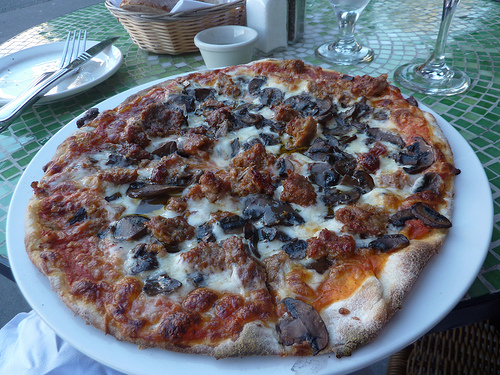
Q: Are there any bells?
A: No, there are no bells.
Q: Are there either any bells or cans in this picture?
A: No, there are no bells or cans.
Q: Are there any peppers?
A: No, there are no peppers.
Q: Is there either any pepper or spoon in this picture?
A: No, there are no peppers or spoons.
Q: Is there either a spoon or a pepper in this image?
A: No, there are no peppers or spoons.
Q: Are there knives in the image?
A: Yes, there is a knife.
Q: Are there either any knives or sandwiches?
A: Yes, there is a knife.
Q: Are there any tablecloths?
A: No, there are no tablecloths.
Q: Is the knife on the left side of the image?
A: Yes, the knife is on the left of the image.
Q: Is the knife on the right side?
A: No, the knife is on the left of the image.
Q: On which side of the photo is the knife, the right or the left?
A: The knife is on the left of the image.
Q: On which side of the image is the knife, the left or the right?
A: The knife is on the left of the image.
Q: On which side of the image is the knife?
A: The knife is on the left of the image.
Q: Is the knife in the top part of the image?
A: Yes, the knife is in the top of the image.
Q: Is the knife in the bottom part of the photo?
A: No, the knife is in the top of the image.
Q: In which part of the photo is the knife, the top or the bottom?
A: The knife is in the top of the image.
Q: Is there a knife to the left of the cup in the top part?
A: Yes, there is a knife to the left of the cup.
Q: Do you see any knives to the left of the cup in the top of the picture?
A: Yes, there is a knife to the left of the cup.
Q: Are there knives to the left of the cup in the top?
A: Yes, there is a knife to the left of the cup.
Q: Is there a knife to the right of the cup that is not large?
A: No, the knife is to the left of the cup.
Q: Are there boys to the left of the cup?
A: No, there is a knife to the left of the cup.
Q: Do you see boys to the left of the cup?
A: No, there is a knife to the left of the cup.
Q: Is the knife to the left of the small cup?
A: Yes, the knife is to the left of the cup.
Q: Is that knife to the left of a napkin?
A: No, the knife is to the left of the cup.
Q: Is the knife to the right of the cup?
A: No, the knife is to the left of the cup.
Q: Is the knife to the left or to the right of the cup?
A: The knife is to the left of the cup.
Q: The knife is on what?
A: The knife is on the plate.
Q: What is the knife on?
A: The knife is on the plate.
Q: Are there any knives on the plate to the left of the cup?
A: Yes, there is a knife on the plate.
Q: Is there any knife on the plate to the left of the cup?
A: Yes, there is a knife on the plate.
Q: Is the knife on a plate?
A: Yes, the knife is on a plate.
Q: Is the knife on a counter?
A: No, the knife is on a plate.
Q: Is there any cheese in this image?
A: Yes, there is cheese.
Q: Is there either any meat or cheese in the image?
A: Yes, there is cheese.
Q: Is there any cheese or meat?
A: Yes, there is cheese.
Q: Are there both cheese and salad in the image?
A: No, there is cheese but no salad.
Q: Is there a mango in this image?
A: No, there are no mangoes.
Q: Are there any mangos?
A: No, there are no mangos.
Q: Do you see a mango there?
A: No, there are no mangoes.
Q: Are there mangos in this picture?
A: No, there are no mangos.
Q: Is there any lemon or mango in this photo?
A: No, there are no mangoes or lemons.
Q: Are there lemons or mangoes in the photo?
A: No, there are no mangoes or lemons.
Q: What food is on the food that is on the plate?
A: The food is cheese.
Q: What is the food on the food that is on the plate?
A: The food is cheese.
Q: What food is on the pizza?
A: The food is cheese.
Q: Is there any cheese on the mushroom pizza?
A: Yes, there is cheese on the pizza.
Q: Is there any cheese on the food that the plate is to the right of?
A: Yes, there is cheese on the pizza.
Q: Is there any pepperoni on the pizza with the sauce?
A: No, there is cheese on the pizza.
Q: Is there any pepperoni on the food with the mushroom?
A: No, there is cheese on the pizza.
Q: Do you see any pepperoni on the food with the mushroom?
A: No, there is cheese on the pizza.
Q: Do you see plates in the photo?
A: Yes, there is a plate.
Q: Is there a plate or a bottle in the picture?
A: Yes, there is a plate.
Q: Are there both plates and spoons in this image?
A: No, there is a plate but no spoons.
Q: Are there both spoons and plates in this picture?
A: No, there is a plate but no spoons.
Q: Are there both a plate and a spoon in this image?
A: No, there is a plate but no spoons.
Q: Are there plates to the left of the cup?
A: Yes, there is a plate to the left of the cup.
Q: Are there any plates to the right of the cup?
A: No, the plate is to the left of the cup.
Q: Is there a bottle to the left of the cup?
A: No, there is a plate to the left of the cup.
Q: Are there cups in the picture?
A: Yes, there is a cup.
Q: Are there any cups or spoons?
A: Yes, there is a cup.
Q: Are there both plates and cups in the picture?
A: Yes, there are both a cup and a plate.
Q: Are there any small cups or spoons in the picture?
A: Yes, there is a small cup.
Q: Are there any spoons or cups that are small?
A: Yes, the cup is small.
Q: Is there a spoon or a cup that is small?
A: Yes, the cup is small.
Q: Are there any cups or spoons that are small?
A: Yes, the cup is small.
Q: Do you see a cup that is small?
A: Yes, there is a small cup.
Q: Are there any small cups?
A: Yes, there is a small cup.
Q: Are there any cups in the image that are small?
A: Yes, there is a cup that is small.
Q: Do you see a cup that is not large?
A: Yes, there is a small cup.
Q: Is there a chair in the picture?
A: No, there are no chairs.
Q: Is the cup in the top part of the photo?
A: Yes, the cup is in the top of the image.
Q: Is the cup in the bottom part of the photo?
A: No, the cup is in the top of the image.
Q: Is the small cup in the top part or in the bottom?
A: The cup is in the top of the image.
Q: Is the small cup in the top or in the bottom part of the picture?
A: The cup is in the top of the image.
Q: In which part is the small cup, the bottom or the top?
A: The cup is in the top of the image.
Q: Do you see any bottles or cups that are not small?
A: No, there is a cup but it is small.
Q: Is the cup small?
A: Yes, the cup is small.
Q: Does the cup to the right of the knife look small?
A: Yes, the cup is small.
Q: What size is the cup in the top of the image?
A: The cup is small.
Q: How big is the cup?
A: The cup is small.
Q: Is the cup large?
A: No, the cup is small.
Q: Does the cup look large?
A: No, the cup is small.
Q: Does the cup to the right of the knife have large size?
A: No, the cup is small.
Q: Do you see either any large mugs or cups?
A: No, there is a cup but it is small.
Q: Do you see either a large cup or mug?
A: No, there is a cup but it is small.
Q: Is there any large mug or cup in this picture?
A: No, there is a cup but it is small.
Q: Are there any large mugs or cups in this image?
A: No, there is a cup but it is small.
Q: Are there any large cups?
A: No, there is a cup but it is small.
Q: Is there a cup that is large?
A: No, there is a cup but it is small.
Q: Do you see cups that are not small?
A: No, there is a cup but it is small.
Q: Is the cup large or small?
A: The cup is small.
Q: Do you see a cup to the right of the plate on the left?
A: Yes, there is a cup to the right of the plate.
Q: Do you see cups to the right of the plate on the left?
A: Yes, there is a cup to the right of the plate.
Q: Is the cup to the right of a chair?
A: No, the cup is to the right of the plate.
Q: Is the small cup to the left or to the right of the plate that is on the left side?
A: The cup is to the right of the plate.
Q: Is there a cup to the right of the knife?
A: Yes, there is a cup to the right of the knife.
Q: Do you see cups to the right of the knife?
A: Yes, there is a cup to the right of the knife.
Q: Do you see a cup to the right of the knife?
A: Yes, there is a cup to the right of the knife.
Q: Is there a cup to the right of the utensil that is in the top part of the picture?
A: Yes, there is a cup to the right of the knife.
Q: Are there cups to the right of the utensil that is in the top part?
A: Yes, there is a cup to the right of the knife.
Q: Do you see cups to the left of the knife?
A: No, the cup is to the right of the knife.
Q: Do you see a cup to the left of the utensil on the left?
A: No, the cup is to the right of the knife.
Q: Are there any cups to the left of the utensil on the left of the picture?
A: No, the cup is to the right of the knife.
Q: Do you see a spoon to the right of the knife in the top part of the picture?
A: No, there is a cup to the right of the knife.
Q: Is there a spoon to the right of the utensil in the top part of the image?
A: No, there is a cup to the right of the knife.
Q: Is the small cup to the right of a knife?
A: Yes, the cup is to the right of a knife.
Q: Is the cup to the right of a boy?
A: No, the cup is to the right of a knife.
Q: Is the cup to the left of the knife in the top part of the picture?
A: No, the cup is to the right of the knife.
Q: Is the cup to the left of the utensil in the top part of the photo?
A: No, the cup is to the right of the knife.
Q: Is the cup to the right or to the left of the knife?
A: The cup is to the right of the knife.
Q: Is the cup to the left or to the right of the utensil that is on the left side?
A: The cup is to the right of the knife.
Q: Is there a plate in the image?
A: Yes, there is a plate.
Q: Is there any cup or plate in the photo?
A: Yes, there is a plate.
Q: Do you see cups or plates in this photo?
A: Yes, there is a plate.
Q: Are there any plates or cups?
A: Yes, there is a plate.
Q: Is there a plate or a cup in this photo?
A: Yes, there is a plate.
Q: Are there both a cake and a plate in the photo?
A: No, there is a plate but no cakes.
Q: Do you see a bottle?
A: No, there are no bottles.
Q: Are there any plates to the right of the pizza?
A: Yes, there is a plate to the right of the pizza.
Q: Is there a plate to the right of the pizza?
A: Yes, there is a plate to the right of the pizza.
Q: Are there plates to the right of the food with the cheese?
A: Yes, there is a plate to the right of the pizza.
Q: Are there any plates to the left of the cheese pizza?
A: No, the plate is to the right of the pizza.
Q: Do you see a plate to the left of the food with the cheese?
A: No, the plate is to the right of the pizza.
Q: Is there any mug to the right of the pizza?
A: No, there is a plate to the right of the pizza.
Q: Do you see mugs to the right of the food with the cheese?
A: No, there is a plate to the right of the pizza.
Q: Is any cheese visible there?
A: Yes, there is cheese.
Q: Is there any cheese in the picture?
A: Yes, there is cheese.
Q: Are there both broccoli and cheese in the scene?
A: No, there is cheese but no broccoli.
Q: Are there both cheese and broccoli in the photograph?
A: No, there is cheese but no broccoli.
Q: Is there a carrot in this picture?
A: No, there are no carrots.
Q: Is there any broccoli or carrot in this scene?
A: No, there are no carrots or broccoli.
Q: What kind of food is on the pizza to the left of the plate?
A: The food is cheese.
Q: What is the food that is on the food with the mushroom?
A: The food is cheese.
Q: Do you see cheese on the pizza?
A: Yes, there is cheese on the pizza.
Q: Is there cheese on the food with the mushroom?
A: Yes, there is cheese on the pizza.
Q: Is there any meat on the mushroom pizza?
A: No, there is cheese on the pizza.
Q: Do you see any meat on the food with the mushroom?
A: No, there is cheese on the pizza.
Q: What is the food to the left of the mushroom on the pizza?
A: The food is cheese.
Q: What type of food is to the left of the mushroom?
A: The food is cheese.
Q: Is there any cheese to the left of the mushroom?
A: Yes, there is cheese to the left of the mushroom.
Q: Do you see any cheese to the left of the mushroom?
A: Yes, there is cheese to the left of the mushroom.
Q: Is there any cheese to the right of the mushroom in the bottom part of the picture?
A: No, the cheese is to the left of the mushroom.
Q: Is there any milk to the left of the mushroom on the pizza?
A: No, there is cheese to the left of the mushroom.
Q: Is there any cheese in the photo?
A: Yes, there is cheese.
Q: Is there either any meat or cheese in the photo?
A: Yes, there is cheese.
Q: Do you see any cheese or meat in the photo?
A: Yes, there is cheese.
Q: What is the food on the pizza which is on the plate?
A: The food is cheese.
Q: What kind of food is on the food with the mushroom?
A: The food is cheese.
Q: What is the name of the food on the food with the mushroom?
A: The food is cheese.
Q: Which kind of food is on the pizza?
A: The food is cheese.